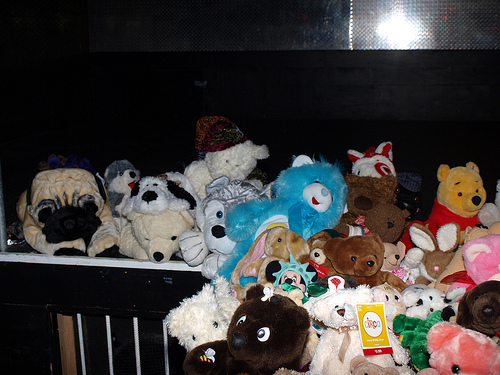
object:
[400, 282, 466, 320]
stuffed animal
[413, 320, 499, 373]
bear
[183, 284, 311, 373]
bear